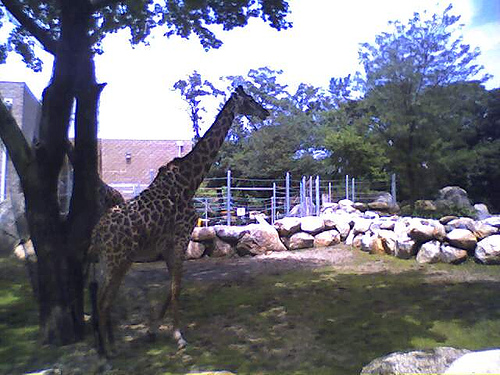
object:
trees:
[345, 0, 500, 209]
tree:
[5, 0, 287, 348]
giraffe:
[83, 83, 272, 358]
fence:
[198, 171, 398, 225]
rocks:
[184, 185, 500, 266]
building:
[100, 139, 151, 179]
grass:
[233, 281, 360, 341]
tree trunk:
[2, 49, 110, 348]